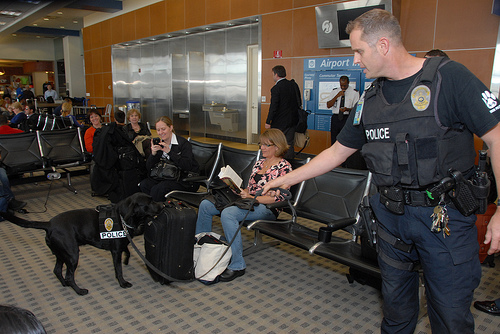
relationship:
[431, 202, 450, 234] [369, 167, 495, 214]
keys on belt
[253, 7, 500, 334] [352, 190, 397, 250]
man gun in a thigh holster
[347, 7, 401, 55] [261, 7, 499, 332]
hair on man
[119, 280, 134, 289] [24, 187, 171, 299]
paw on dog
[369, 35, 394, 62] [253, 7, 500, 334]
ear on man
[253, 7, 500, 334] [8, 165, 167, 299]
man with dog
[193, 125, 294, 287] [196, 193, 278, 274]
woman with jeans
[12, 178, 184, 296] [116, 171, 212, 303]
dog with baggage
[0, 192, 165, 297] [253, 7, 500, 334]
dog with man